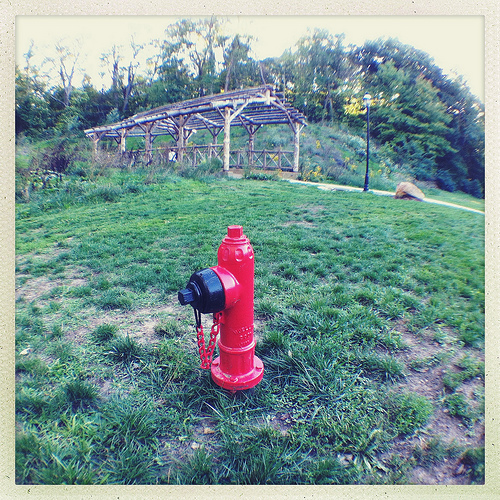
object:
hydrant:
[180, 223, 265, 392]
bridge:
[83, 82, 308, 176]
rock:
[394, 180, 427, 201]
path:
[287, 176, 485, 216]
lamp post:
[362, 104, 372, 193]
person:
[167, 149, 178, 165]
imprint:
[235, 326, 253, 343]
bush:
[298, 163, 326, 182]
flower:
[300, 158, 326, 182]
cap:
[177, 267, 224, 313]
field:
[17, 121, 484, 485]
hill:
[37, 91, 447, 193]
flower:
[314, 140, 322, 148]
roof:
[85, 84, 313, 141]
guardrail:
[94, 143, 228, 172]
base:
[211, 354, 264, 392]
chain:
[192, 307, 227, 371]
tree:
[15, 15, 486, 198]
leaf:
[24, 66, 30, 72]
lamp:
[362, 94, 373, 106]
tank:
[218, 240, 255, 375]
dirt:
[161, 412, 221, 473]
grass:
[14, 122, 483, 485]